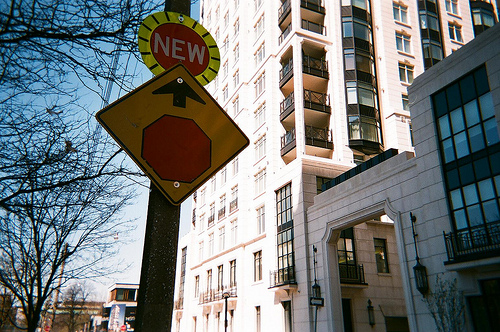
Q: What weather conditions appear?
A: It is clear.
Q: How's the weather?
A: It is clear.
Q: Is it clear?
A: Yes, it is clear.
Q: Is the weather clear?
A: Yes, it is clear.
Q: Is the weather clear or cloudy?
A: It is clear.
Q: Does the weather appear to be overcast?
A: No, it is clear.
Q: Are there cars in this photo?
A: No, there are no cars.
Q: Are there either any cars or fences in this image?
A: No, there are no cars or fences.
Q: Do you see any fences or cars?
A: No, there are no cars or fences.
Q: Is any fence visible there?
A: No, there are no fences.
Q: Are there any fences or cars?
A: No, there are no fences or cars.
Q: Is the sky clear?
A: Yes, the sky is clear.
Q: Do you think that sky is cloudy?
A: No, the sky is clear.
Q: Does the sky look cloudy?
A: No, the sky is clear.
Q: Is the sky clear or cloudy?
A: The sky is clear.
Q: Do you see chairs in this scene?
A: No, there are no chairs.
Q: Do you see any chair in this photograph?
A: No, there are no chairs.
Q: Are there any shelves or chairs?
A: No, there are no chairs or shelves.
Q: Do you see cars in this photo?
A: No, there are no cars.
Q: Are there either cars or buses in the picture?
A: No, there are no cars or buses.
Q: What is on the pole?
A: The sign is on the pole.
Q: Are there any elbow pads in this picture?
A: No, there are no elbow pads.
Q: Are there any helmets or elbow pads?
A: No, there are no elbow pads or helmets.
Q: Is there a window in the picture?
A: Yes, there is a window.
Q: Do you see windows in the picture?
A: Yes, there is a window.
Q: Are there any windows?
A: Yes, there is a window.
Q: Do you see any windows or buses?
A: Yes, there is a window.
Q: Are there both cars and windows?
A: No, there is a window but no cars.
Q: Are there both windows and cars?
A: No, there is a window but no cars.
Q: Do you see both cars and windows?
A: No, there is a window but no cars.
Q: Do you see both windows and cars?
A: No, there is a window but no cars.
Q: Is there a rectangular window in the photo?
A: Yes, there is a rectangular window.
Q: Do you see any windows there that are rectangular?
A: Yes, there is a window that is rectangular.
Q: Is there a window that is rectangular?
A: Yes, there is a window that is rectangular.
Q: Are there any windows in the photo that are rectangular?
A: Yes, there is a window that is rectangular.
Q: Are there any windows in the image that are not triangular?
A: Yes, there is a rectangular window.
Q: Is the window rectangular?
A: Yes, the window is rectangular.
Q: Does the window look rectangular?
A: Yes, the window is rectangular.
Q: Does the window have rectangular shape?
A: Yes, the window is rectangular.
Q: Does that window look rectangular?
A: Yes, the window is rectangular.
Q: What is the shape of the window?
A: The window is rectangular.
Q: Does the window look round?
A: No, the window is rectangular.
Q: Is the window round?
A: No, the window is rectangular.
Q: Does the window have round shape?
A: No, the window is rectangular.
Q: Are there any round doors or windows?
A: No, there is a window but it is rectangular.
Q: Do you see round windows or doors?
A: No, there is a window but it is rectangular.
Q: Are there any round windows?
A: No, there is a window but it is rectangular.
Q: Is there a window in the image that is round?
A: No, there is a window but it is rectangular.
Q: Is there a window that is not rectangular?
A: No, there is a window but it is rectangular.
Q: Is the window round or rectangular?
A: The window is rectangular.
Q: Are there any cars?
A: No, there are no cars.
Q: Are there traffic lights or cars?
A: No, there are no cars or traffic lights.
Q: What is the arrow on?
A: The arrow is on the sign.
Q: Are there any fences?
A: No, there are no fences.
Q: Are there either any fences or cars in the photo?
A: No, there are no fences or cars.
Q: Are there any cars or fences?
A: No, there are no fences or cars.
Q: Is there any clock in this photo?
A: No, there are no clocks.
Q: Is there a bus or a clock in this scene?
A: No, there are no clocks or buses.